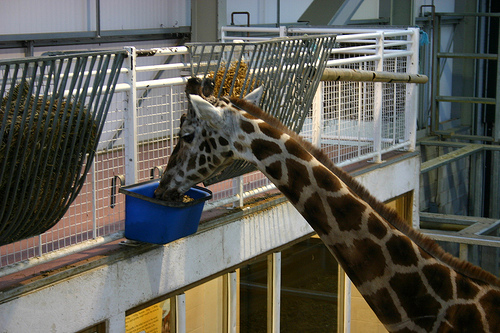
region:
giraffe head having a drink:
[115, 64, 271, 234]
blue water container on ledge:
[100, 172, 218, 242]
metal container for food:
[259, 37, 348, 117]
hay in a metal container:
[3, 57, 111, 249]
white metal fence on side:
[331, 90, 425, 152]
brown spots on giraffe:
[248, 113, 433, 308]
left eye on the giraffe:
[175, 128, 203, 143]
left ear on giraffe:
[188, 90, 233, 127]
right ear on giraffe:
[241, 80, 271, 107]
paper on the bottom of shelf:
[126, 295, 168, 331]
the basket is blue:
[128, 184, 213, 234]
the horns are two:
[177, 75, 234, 105]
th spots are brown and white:
[293, 173, 409, 298]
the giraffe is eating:
[161, 91, 497, 319]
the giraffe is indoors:
[172, 70, 493, 325]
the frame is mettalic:
[130, 30, 430, 135]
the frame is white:
[115, 37, 437, 192]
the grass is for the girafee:
[19, 91, 99, 234]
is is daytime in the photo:
[8, 13, 460, 328]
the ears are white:
[183, 94, 233, 126]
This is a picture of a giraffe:
[146, 107, 366, 305]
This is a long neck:
[283, 152, 455, 292]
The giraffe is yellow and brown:
[281, 88, 438, 275]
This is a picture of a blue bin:
[128, 181, 226, 253]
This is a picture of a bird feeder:
[10, 60, 137, 233]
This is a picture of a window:
[182, 253, 277, 325]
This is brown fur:
[265, 111, 429, 267]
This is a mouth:
[145, 160, 210, 212]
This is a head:
[157, 109, 288, 206]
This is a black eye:
[165, 110, 218, 166]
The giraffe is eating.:
[148, 88, 358, 268]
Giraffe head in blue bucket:
[127, 96, 245, 253]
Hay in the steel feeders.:
[20, 110, 100, 196]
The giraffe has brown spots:
[368, 202, 462, 302]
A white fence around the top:
[161, 42, 434, 141]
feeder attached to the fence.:
[183, 53, 343, 136]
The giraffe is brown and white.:
[299, 144, 449, 266]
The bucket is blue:
[118, 170, 188, 230]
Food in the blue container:
[162, 191, 202, 221]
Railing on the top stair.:
[351, 38, 481, 147]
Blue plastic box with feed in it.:
[118, 185, 213, 243]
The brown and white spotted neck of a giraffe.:
[249, 104, 446, 329]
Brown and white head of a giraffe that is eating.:
[153, 82, 268, 201]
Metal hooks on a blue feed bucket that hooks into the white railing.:
[108, 164, 165, 207]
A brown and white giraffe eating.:
[153, 80, 499, 330]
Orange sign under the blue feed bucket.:
[118, 299, 167, 331]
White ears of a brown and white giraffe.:
[184, 81, 269, 119]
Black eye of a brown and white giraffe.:
[179, 128, 195, 143]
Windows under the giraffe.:
[163, 229, 380, 331]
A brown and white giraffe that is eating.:
[158, 84, 498, 331]